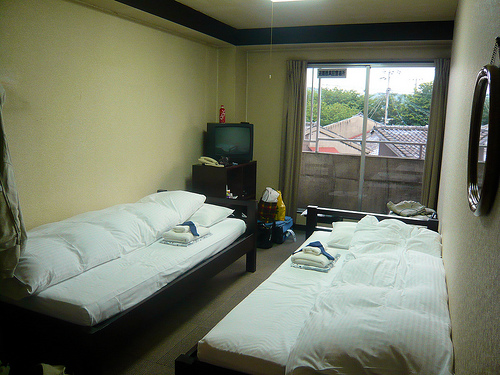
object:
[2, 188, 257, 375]
bed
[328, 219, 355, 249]
pillow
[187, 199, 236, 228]
pillow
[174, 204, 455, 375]
bed